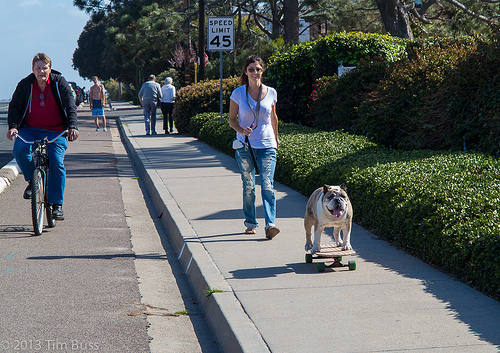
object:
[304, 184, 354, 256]
dog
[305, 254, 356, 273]
skateboar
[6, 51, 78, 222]
man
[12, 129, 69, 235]
bike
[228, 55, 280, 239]
woman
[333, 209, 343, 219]
tongue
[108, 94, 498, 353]
sidewalk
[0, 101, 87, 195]
curb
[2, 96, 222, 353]
road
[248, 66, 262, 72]
sunglasses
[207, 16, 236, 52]
sign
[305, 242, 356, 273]
skateboard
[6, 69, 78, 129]
jacket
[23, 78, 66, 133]
shirt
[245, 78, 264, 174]
leash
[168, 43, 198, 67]
flowers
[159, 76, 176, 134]
old lady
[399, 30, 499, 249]
bushes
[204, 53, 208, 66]
sign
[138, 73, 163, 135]
elderly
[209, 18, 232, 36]
speed limit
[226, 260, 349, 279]
shadow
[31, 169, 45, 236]
front tire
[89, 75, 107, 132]
man